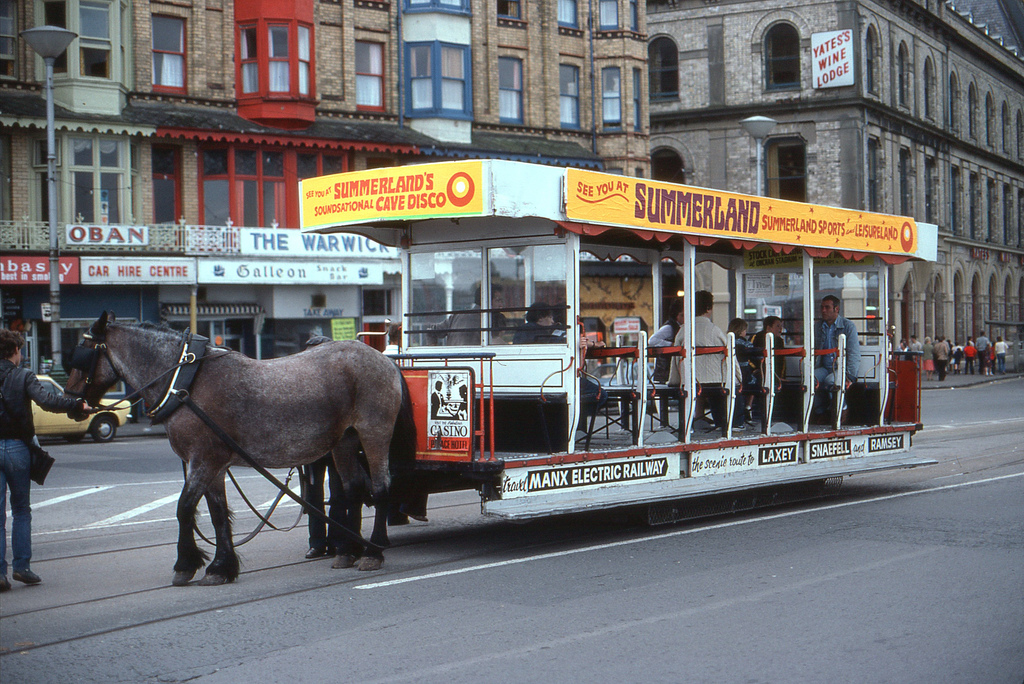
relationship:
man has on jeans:
[0, 282, 85, 591] [10, 489, 39, 574]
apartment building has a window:
[19, 5, 307, 215] [75, 14, 128, 81]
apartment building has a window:
[0, 0, 647, 217] [486, 42, 536, 123]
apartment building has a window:
[0, 0, 647, 217] [481, 35, 536, 124]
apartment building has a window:
[0, 0, 647, 217] [486, 35, 534, 133]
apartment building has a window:
[0, 0, 647, 217] [561, 46, 588, 131]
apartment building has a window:
[0, 0, 647, 217] [289, 22, 320, 98]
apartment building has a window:
[0, 0, 647, 217] [261, 13, 301, 100]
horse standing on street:
[63, 317, 412, 592] [399, 554, 883, 667]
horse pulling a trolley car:
[63, 317, 412, 592] [423, 139, 927, 502]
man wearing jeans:
[0, 324, 71, 592] [11, 448, 38, 587]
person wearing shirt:
[963, 338, 981, 367] [959, 335, 977, 359]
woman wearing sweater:
[664, 284, 732, 438] [677, 312, 734, 382]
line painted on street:
[359, 511, 815, 589] [52, 459, 1012, 680]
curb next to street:
[921, 366, 1014, 399] [828, 383, 1019, 680]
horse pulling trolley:
[55, 296, 455, 601] [261, 130, 974, 535]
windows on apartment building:
[129, 89, 464, 265] [0, 0, 647, 217]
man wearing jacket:
[0, 324, 71, 592] [6, 363, 76, 467]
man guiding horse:
[0, 324, 71, 592] [55, 294, 492, 580]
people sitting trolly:
[442, 289, 939, 484] [286, 134, 945, 519]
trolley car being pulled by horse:
[351, 148, 911, 504] [45, 305, 437, 593]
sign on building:
[811, 26, 866, 102] [662, 6, 985, 402]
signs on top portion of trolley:
[300, 145, 946, 260] [259, 153, 988, 577]